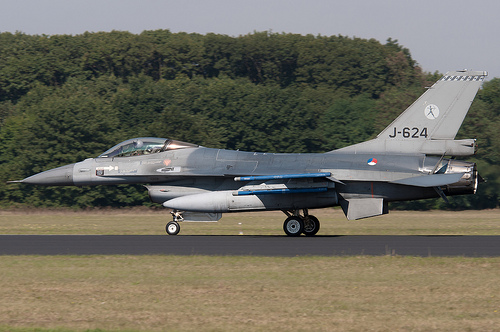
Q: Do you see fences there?
A: No, there are no fences.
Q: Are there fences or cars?
A: No, there are no fences or cars.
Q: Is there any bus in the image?
A: No, there are no buses.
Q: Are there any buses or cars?
A: No, there are no buses or cars.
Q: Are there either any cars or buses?
A: No, there are no buses or cars.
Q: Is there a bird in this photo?
A: No, there are no birds.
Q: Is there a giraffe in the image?
A: No, there are no giraffes.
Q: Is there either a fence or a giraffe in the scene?
A: No, there are no giraffes or fences.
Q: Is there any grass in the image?
A: Yes, there is grass.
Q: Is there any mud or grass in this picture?
A: Yes, there is grass.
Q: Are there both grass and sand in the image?
A: No, there is grass but no sand.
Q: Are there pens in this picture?
A: No, there are no pens.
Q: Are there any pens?
A: No, there are no pens.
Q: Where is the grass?
A: The grass is on the ground.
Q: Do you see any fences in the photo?
A: No, there are no fences.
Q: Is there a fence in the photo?
A: No, there are no fences.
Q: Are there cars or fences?
A: No, there are no fences or cars.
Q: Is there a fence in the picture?
A: No, there are no fences.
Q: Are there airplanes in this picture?
A: Yes, there is an airplane.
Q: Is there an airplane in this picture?
A: Yes, there is an airplane.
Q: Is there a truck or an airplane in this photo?
A: Yes, there is an airplane.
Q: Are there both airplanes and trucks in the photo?
A: No, there is an airplane but no trucks.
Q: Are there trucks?
A: No, there are no trucks.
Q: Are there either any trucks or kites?
A: No, there are no trucks or kites.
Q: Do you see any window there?
A: Yes, there is a window.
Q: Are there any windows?
A: Yes, there is a window.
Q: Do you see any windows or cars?
A: Yes, there is a window.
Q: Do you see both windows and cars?
A: No, there is a window but no cars.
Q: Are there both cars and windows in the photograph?
A: No, there is a window but no cars.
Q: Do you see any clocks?
A: No, there are no clocks.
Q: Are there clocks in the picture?
A: No, there are no clocks.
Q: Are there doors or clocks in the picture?
A: No, there are no clocks or doors.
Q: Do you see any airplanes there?
A: Yes, there is an airplane.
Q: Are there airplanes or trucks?
A: Yes, there is an airplane.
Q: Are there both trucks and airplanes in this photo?
A: No, there is an airplane but no trucks.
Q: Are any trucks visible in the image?
A: No, there are no trucks.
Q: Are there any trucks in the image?
A: No, there are no trucks.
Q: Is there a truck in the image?
A: No, there are no trucks.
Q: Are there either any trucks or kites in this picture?
A: No, there are no trucks or kites.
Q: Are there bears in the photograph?
A: No, there are no bears.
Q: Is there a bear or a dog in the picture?
A: No, there are no bears or dogs.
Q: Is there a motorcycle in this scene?
A: No, there are no motorcycles.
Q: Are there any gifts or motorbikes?
A: No, there are no motorbikes or gifts.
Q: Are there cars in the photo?
A: No, there are no cars.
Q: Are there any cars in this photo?
A: No, there are no cars.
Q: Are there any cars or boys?
A: No, there are no cars or boys.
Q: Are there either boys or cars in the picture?
A: No, there are no cars or boys.